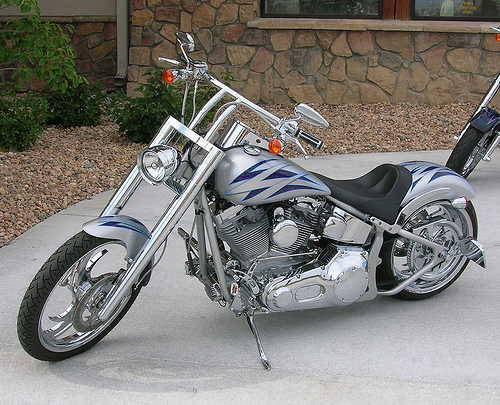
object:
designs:
[216, 148, 325, 210]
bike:
[15, 31, 483, 374]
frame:
[90, 59, 479, 324]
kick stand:
[247, 311, 272, 372]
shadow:
[47, 342, 286, 397]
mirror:
[286, 100, 328, 131]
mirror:
[172, 30, 197, 70]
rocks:
[3, 97, 475, 243]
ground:
[4, 103, 497, 403]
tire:
[15, 229, 142, 364]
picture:
[1, 2, 497, 402]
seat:
[321, 162, 415, 225]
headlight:
[138, 141, 177, 185]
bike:
[442, 20, 498, 178]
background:
[0, 2, 499, 249]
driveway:
[0, 150, 498, 401]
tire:
[383, 196, 480, 297]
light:
[268, 140, 283, 155]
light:
[163, 66, 175, 86]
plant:
[104, 62, 228, 143]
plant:
[1, 0, 101, 148]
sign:
[414, 0, 494, 23]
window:
[262, 0, 477, 20]